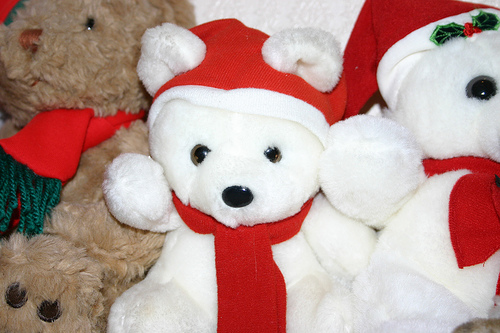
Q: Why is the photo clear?
A: Its during the day.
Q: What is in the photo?
A: Teddybears.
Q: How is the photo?
A: Clear.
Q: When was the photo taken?
A: Daytime.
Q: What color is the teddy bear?
A: White.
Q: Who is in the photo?
A: Nobody.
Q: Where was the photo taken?
A: On the shelf.